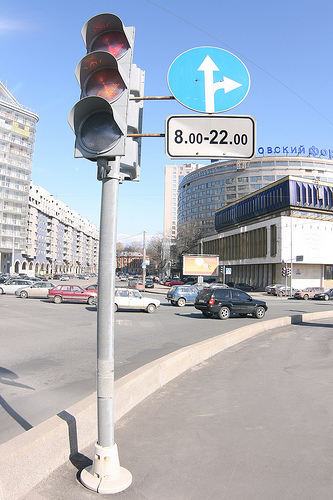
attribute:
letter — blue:
[282, 145, 290, 157]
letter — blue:
[295, 143, 306, 156]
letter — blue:
[257, 146, 267, 157]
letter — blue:
[265, 145, 274, 157]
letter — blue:
[273, 146, 282, 158]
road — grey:
[3, 273, 332, 498]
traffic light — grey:
[67, 10, 147, 184]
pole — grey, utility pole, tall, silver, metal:
[93, 174, 121, 454]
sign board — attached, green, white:
[165, 43, 253, 117]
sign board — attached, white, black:
[163, 113, 258, 163]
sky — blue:
[0, 1, 332, 241]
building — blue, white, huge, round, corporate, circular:
[173, 154, 332, 255]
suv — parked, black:
[192, 285, 269, 322]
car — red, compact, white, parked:
[43, 281, 101, 308]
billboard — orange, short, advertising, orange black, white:
[178, 253, 220, 278]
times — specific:
[172, 124, 250, 149]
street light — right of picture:
[218, 262, 230, 286]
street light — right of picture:
[279, 255, 293, 295]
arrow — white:
[197, 52, 222, 112]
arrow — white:
[210, 71, 244, 98]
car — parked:
[91, 286, 162, 318]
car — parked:
[167, 283, 203, 309]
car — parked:
[13, 277, 60, 300]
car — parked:
[1, 275, 37, 298]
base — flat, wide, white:
[76, 440, 134, 500]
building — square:
[194, 175, 332, 298]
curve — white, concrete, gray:
[4, 309, 333, 498]